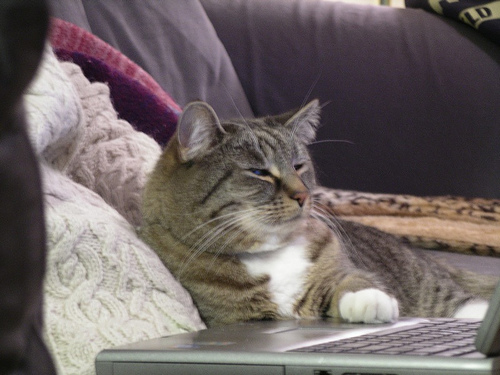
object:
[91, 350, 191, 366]
edge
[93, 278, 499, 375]
laptop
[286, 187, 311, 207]
nose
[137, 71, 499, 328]
cat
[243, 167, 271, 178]
eye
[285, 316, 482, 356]
keyboard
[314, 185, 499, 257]
matress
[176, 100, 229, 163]
ear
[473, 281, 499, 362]
screen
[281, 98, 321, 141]
ear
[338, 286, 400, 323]
paw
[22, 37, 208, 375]
afghan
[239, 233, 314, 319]
fur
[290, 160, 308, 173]
eye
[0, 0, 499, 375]
couch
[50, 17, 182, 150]
blanket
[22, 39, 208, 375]
blanket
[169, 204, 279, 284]
mustaches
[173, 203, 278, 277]
whiskers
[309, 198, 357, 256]
whiskers